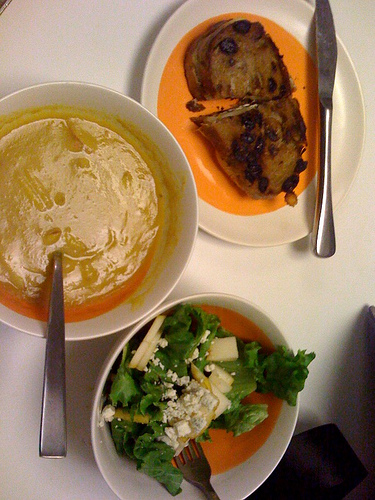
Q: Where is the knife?
A: On the plate.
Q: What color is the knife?
A: Silver.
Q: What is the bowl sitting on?
A: The table.